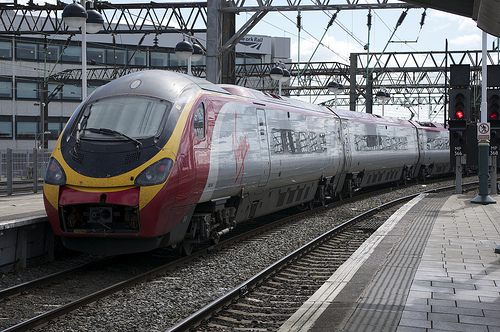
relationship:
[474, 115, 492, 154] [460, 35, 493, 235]
no walking sign on post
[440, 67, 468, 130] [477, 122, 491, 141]
ligh on no walking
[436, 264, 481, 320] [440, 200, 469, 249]
bricks on sidewalk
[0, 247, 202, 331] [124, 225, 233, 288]
train rail on train rail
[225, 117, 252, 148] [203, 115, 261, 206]
red virgin sign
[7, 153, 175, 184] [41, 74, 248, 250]
headlight on train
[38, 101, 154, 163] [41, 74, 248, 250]
wiper blade on train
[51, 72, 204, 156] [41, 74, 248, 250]
windshield on train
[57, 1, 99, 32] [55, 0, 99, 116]
lights on light post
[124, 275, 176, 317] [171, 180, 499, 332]
gravel on track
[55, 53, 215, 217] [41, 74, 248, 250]
front of train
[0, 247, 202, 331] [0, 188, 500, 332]
train rail in platform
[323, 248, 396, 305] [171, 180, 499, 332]
curb of track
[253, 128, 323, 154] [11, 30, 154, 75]
windows of building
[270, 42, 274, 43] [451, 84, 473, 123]
"a traffic light"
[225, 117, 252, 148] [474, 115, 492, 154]
red and white traffic sign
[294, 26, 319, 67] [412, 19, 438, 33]
clouds in sky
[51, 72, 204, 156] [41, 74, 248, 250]
windshield wiper train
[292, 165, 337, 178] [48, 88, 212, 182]
silver train engine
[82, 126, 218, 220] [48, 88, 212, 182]
red yellow and black train engine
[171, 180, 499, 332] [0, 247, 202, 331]
track of train rail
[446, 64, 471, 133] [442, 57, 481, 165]
ligh train light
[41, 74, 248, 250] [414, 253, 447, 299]
train boarding platform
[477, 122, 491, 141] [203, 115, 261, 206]
no walking entry sign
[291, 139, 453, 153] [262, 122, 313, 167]
long train window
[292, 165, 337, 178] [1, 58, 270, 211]
silver train engine"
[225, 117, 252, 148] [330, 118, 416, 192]
red and silver train car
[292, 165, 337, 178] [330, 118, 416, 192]
silver train car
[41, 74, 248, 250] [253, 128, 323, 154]
train passenger windows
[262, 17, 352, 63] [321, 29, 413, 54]
overhead power lines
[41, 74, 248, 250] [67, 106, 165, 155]
large train windshield wiper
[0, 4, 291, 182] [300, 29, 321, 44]
building building distance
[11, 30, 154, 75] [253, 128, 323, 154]
building has windows